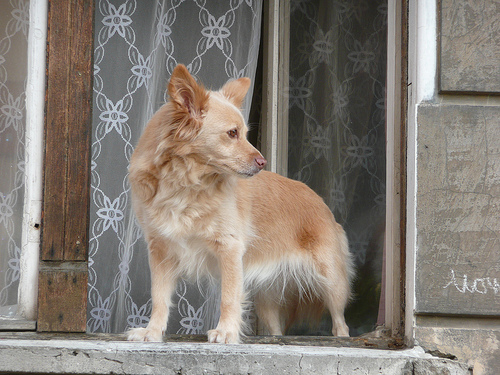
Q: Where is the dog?
A: On the ledge.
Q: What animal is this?
A: A dog.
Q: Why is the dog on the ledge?
A: It is looking outside.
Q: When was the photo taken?
A: Daytime.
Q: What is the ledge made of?
A: Concrete.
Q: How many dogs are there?
A: One.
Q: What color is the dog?
A: Light brown.